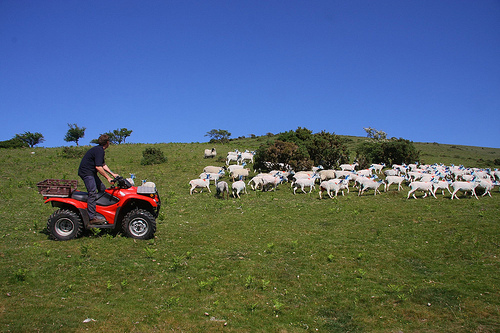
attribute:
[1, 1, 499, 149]
sky — blue, bright, clear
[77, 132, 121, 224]
man — young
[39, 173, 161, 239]
wheeler — red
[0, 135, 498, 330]
grass — green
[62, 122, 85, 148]
tree — green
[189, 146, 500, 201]
cattle — white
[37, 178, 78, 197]
basket — brown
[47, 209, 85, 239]
wheel — black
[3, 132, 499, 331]
hill — green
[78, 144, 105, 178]
shirt — black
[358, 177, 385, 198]
sheep — white